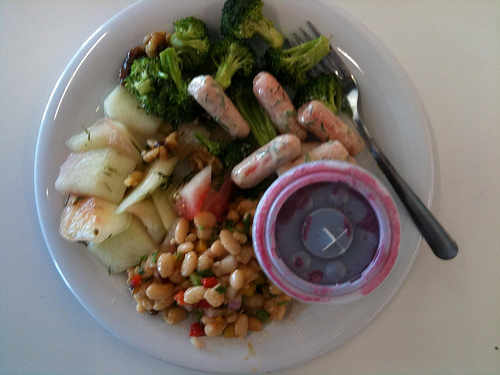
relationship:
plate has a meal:
[32, 0, 436, 375] [58, 0, 404, 350]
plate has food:
[32, 0, 436, 375] [58, 0, 404, 350]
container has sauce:
[253, 161, 402, 306] [276, 179, 381, 287]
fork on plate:
[285, 18, 460, 263] [32, 0, 436, 375]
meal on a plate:
[58, 0, 404, 350] [32, 0, 436, 375]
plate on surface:
[32, 0, 436, 375] [0, 0, 499, 375]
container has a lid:
[253, 161, 402, 306] [252, 159, 403, 300]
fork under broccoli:
[285, 18, 460, 263] [267, 37, 332, 90]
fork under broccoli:
[285, 18, 460, 263] [293, 74, 343, 112]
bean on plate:
[175, 216, 191, 244] [32, 0, 436, 375]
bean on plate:
[157, 251, 176, 281] [32, 0, 436, 375]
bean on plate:
[182, 249, 198, 280] [32, 0, 436, 375]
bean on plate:
[184, 285, 207, 305] [32, 0, 436, 375]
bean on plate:
[231, 267, 245, 292] [32, 0, 436, 375]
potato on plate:
[104, 85, 164, 134] [32, 0, 436, 375]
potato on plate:
[65, 117, 148, 167] [32, 0, 436, 375]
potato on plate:
[53, 147, 137, 204] [32, 0, 436, 375]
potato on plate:
[56, 192, 131, 247] [32, 0, 436, 375]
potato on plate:
[88, 223, 157, 276] [32, 0, 436, 375]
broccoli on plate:
[169, 15, 211, 71] [32, 0, 436, 375]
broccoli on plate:
[209, 39, 257, 90] [32, 0, 436, 375]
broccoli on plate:
[221, 0, 286, 51] [32, 0, 436, 375]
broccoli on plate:
[267, 37, 332, 90] [32, 0, 436, 375]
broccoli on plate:
[293, 74, 343, 112] [32, 0, 436, 375]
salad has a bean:
[127, 211, 292, 350] [175, 216, 191, 244]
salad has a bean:
[127, 211, 292, 350] [157, 251, 176, 281]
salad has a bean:
[127, 211, 292, 350] [182, 249, 198, 280]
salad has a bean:
[127, 211, 292, 350] [184, 285, 207, 305]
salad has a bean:
[127, 211, 292, 350] [231, 267, 245, 292]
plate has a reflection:
[32, 0, 436, 375] [50, 31, 115, 123]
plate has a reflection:
[32, 0, 436, 375] [336, 44, 367, 79]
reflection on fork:
[343, 85, 361, 122] [285, 18, 460, 263]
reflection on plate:
[50, 31, 115, 123] [32, 0, 436, 375]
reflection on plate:
[336, 44, 367, 79] [32, 0, 436, 375]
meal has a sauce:
[58, 0, 404, 350] [276, 179, 381, 287]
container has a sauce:
[253, 161, 402, 306] [276, 179, 381, 287]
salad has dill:
[55, 84, 228, 271] [83, 124, 93, 142]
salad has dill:
[55, 84, 228, 271] [102, 181, 114, 194]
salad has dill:
[55, 84, 228, 271] [103, 162, 121, 176]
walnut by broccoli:
[118, 46, 146, 83] [129, 55, 164, 100]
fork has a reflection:
[285, 18, 460, 263] [343, 85, 361, 122]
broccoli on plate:
[129, 55, 164, 100] [32, 0, 436, 375]